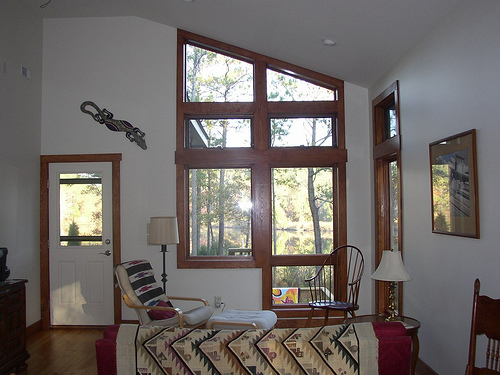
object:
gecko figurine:
[79, 98, 146, 149]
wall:
[39, 16, 376, 326]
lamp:
[370, 249, 412, 320]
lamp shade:
[370, 249, 412, 282]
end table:
[342, 312, 420, 374]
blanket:
[110, 259, 179, 322]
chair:
[114, 255, 217, 328]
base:
[377, 282, 403, 321]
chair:
[304, 243, 367, 327]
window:
[185, 38, 338, 311]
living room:
[0, 1, 499, 374]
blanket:
[114, 325, 379, 374]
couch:
[94, 319, 412, 373]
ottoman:
[207, 305, 277, 331]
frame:
[176, 25, 347, 321]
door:
[49, 160, 115, 327]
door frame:
[37, 151, 120, 329]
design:
[133, 323, 359, 374]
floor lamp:
[147, 213, 181, 295]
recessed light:
[321, 33, 335, 50]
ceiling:
[26, 1, 461, 88]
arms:
[305, 274, 362, 287]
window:
[56, 172, 104, 249]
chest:
[2, 275, 34, 374]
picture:
[427, 126, 481, 240]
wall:
[373, 3, 497, 372]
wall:
[0, 3, 45, 333]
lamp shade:
[145, 213, 180, 246]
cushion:
[115, 259, 213, 324]